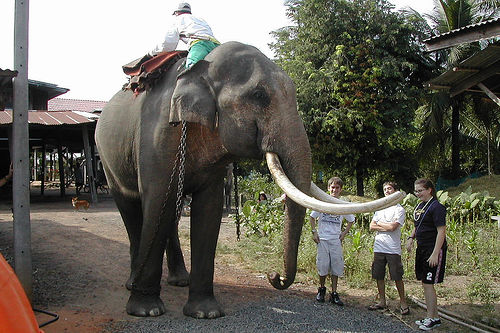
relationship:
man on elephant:
[116, 0, 264, 97] [92, 40, 406, 320]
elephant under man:
[92, 40, 406, 320] [116, 0, 264, 97]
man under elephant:
[147, 3, 219, 71] [69, 16, 409, 330]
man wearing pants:
[147, 3, 219, 71] [166, 1, 223, 72]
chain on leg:
[171, 118, 191, 231] [188, 183, 224, 291]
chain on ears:
[171, 118, 191, 231] [166, 74, 226, 138]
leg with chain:
[188, 183, 224, 291] [171, 118, 191, 231]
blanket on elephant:
[118, 46, 192, 96] [94, 40, 316, 317]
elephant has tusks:
[94, 39, 407, 320] [253, 152, 404, 222]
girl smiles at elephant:
[409, 171, 454, 328] [90, 25, 291, 245]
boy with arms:
[367, 180, 409, 315] [365, 217, 399, 237]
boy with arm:
[314, 176, 359, 297] [343, 214, 357, 246]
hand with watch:
[312, 233, 321, 244] [308, 224, 319, 235]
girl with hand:
[405, 176, 445, 331] [304, 223, 322, 246]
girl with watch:
[405, 176, 445, 331] [310, 225, 320, 241]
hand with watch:
[304, 223, 322, 246] [310, 225, 320, 241]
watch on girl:
[310, 225, 320, 241] [405, 176, 445, 331]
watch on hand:
[310, 225, 320, 241] [304, 223, 322, 246]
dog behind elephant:
[69, 193, 94, 214] [94, 39, 407, 320]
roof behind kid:
[421, 18, 498, 56] [307, 175, 354, 306]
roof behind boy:
[421, 18, 498, 56] [367, 180, 409, 315]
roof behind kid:
[421, 18, 498, 56] [404, 177, 447, 331]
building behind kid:
[420, 15, 499, 112] [307, 175, 354, 306]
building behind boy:
[420, 15, 499, 112] [367, 180, 409, 315]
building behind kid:
[420, 15, 499, 112] [404, 177, 447, 331]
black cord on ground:
[35, 305, 57, 328] [36, 298, 76, 331]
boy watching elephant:
[367, 180, 409, 315] [84, 33, 346, 293]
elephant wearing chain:
[92, 40, 406, 320] [154, 99, 199, 236]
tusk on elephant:
[259, 153, 399, 219] [94, 40, 316, 317]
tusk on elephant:
[309, 172, 416, 219] [94, 40, 316, 317]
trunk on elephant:
[270, 114, 312, 295] [94, 40, 316, 317]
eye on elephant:
[248, 86, 269, 107] [94, 40, 316, 317]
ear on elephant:
[166, 69, 216, 129] [94, 39, 407, 320]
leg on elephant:
[132, 159, 228, 325] [79, 41, 308, 326]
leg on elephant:
[177, 183, 228, 319] [237, 32, 399, 291]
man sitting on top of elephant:
[147, 3, 219, 71] [94, 39, 407, 320]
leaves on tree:
[339, 43, 371, 135] [249, 0, 412, 219]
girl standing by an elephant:
[405, 176, 445, 331] [94, 39, 407, 320]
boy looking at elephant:
[308, 176, 356, 306] [94, 39, 407, 320]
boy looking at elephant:
[367, 180, 409, 315] [94, 39, 407, 320]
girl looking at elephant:
[405, 176, 445, 331] [94, 39, 407, 320]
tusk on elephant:
[309, 183, 407, 214] [92, 24, 333, 330]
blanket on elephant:
[120, 49, 187, 96] [94, 39, 407, 320]